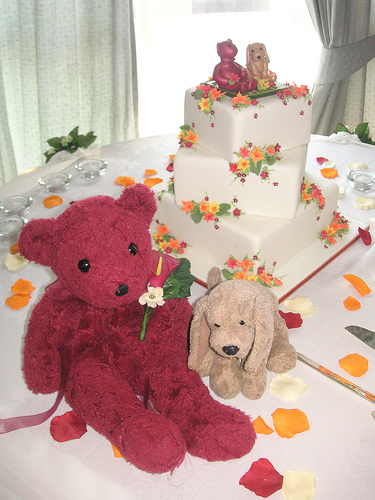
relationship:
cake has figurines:
[149, 38, 340, 271] [215, 37, 257, 93]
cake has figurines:
[149, 38, 340, 271] [241, 38, 277, 88]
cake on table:
[149, 38, 345, 271] [0, 130, 374, 497]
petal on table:
[344, 272, 370, 297] [0, 130, 374, 497]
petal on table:
[340, 297, 363, 313] [0, 130, 374, 497]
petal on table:
[338, 353, 370, 380] [0, 130, 374, 497]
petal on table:
[277, 308, 304, 331] [0, 130, 374, 497]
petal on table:
[286, 296, 315, 318] [0, 130, 374, 497]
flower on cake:
[299, 176, 326, 221] [146, 38, 369, 304]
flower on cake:
[180, 195, 245, 230] [146, 38, 369, 304]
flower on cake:
[228, 141, 283, 186] [146, 38, 369, 304]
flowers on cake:
[279, 80, 314, 116] [146, 38, 369, 304]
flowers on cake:
[190, 76, 229, 119] [146, 38, 369, 304]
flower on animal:
[139, 226, 189, 341] [18, 183, 256, 475]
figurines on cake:
[213, 39, 257, 92] [128, 71, 360, 319]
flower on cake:
[228, 143, 281, 186] [149, 38, 345, 271]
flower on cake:
[177, 122, 196, 147] [149, 38, 345, 271]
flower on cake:
[180, 195, 238, 229] [149, 38, 345, 271]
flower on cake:
[298, 177, 325, 209] [149, 38, 345, 271]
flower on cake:
[151, 218, 185, 254] [149, 38, 345, 271]